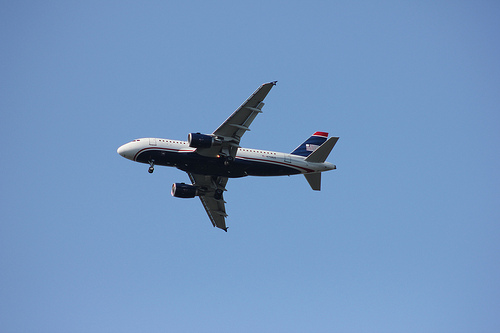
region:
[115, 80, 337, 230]
the plane in the sky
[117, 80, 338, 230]
the plane in mid air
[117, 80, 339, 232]
the flying plane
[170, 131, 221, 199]
the engines on the plane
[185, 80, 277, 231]
the wings on the plane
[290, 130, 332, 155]
the tail on the plane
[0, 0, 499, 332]
the clear blue sky above the plane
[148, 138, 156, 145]
the door on the plane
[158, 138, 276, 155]
the passenger windows on the plane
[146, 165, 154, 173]
the wheels under the plane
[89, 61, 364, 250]
This is an airplane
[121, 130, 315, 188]
This is a fuselage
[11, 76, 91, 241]
Section of a sky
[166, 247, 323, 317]
Section of a sky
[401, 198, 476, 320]
Section of a sky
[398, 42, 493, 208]
Section of a sky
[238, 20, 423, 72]
Section of a sky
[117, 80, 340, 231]
A large white, blue, and red passenger jet flying through the sky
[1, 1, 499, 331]
A clear, blue sky with no clouds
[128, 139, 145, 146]
The cock pit of the jet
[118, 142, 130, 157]
The nose of the jet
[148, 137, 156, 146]
The passenger door of the jet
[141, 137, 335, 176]
The fuselage of the jet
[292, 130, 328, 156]
The tail fin of the jet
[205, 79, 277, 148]
The left wing of the jet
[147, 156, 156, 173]
The landing gear of the jet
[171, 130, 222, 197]
The twin engines of the jet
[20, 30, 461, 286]
this is an airplane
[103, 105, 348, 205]
this is a commercial flight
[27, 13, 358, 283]
the plane is in mid air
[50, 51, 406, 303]
this is a high altitude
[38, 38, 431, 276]
the weather is very clear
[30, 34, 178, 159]
the sky is a hazy blue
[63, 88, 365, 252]
the plane is white, blue, and red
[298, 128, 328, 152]
the plane tail is blue and red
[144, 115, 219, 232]
the plane has two engines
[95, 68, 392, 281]
the plane is in mid flight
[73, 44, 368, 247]
this is a plane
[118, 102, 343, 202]
body of the plane is white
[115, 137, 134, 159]
nose of the plane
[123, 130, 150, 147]
front windows on plane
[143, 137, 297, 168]
row of windows on the plane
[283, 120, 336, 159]
tail of the plane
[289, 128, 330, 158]
tail of the plane is blue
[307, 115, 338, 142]
red trim on tail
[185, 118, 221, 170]
left engine on plane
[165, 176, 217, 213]
right engine on plane